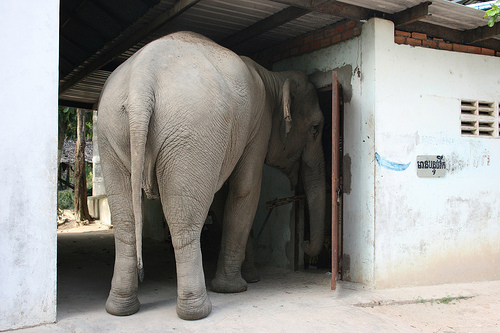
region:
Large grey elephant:
[59, 4, 362, 330]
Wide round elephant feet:
[92, 263, 241, 326]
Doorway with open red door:
[263, 60, 382, 300]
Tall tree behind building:
[55, 89, 105, 226]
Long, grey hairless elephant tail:
[98, 80, 182, 301]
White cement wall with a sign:
[325, 30, 481, 284]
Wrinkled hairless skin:
[156, 72, 227, 238]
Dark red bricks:
[384, 12, 491, 69]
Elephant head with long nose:
[241, 38, 359, 276]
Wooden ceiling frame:
[289, 3, 489, 67]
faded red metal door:
[328, 71, 344, 292]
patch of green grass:
[418, 291, 478, 305]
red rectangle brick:
[394, 29, 411, 36]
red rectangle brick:
[394, 33, 406, 45]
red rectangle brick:
[438, 40, 450, 49]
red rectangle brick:
[456, 42, 470, 49]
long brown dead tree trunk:
[72, 103, 87, 224]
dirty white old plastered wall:
[371, 36, 497, 284]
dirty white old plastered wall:
[1, 1, 56, 326]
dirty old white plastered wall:
[220, 39, 375, 289]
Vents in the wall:
[454, 96, 499, 139]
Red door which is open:
[327, 69, 340, 292]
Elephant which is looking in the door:
[97, 27, 330, 324]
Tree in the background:
[72, 103, 90, 224]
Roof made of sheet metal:
[57, 0, 499, 106]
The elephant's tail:
[125, 65, 153, 287]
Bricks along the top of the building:
[247, 16, 499, 58]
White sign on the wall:
[414, 152, 449, 179]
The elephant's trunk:
[297, 147, 327, 259]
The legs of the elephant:
[95, 126, 267, 319]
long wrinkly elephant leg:
[155, 139, 220, 319]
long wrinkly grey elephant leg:
[93, 136, 145, 316]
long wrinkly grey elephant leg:
[218, 129, 264, 292]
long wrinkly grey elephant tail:
[123, 69, 149, 269]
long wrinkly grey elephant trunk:
[301, 142, 332, 261]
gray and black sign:
[418, 156, 446, 175]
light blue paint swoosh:
[373, 149, 416, 170]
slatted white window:
[457, 96, 499, 141]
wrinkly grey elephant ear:
[278, 74, 296, 136]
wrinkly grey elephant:
[96, 34, 334, 316]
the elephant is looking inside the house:
[96, 29, 327, 319]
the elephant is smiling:
[293, 111, 320, 188]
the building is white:
[255, 40, 495, 290]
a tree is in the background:
[74, 107, 91, 223]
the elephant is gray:
[97, 30, 327, 314]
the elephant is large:
[98, 30, 325, 311]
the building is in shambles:
[263, 14, 497, 284]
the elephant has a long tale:
[130, 82, 147, 269]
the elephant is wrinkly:
[102, 37, 328, 310]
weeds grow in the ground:
[353, 297, 473, 306]